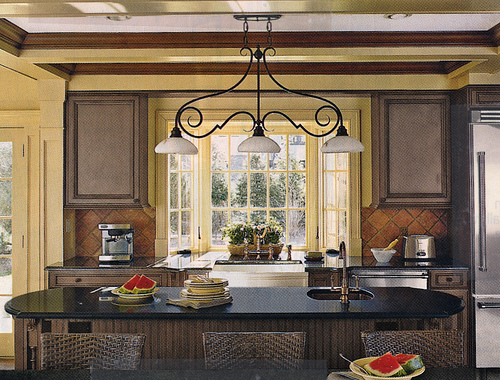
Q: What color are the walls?
A: Yellow.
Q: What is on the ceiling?
A: The lights.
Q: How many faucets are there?
A: One.